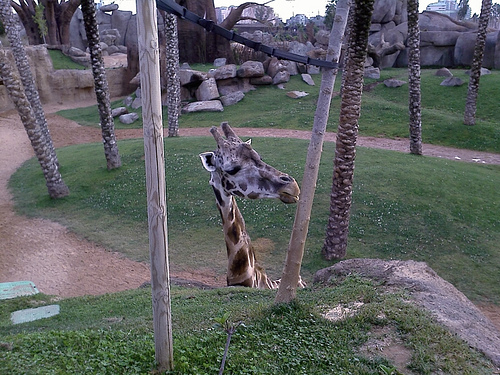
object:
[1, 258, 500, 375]
hill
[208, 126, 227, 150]
horn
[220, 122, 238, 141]
horn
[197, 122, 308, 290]
giraffe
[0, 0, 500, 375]
zoo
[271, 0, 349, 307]
tree trunk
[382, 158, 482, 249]
green grass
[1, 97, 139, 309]
path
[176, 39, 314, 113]
boulders/rocks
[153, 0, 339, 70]
black strap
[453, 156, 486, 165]
water puddle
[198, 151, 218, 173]
right ear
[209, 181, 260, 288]
neck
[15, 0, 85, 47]
tree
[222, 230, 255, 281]
brown spots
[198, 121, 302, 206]
giraffe's head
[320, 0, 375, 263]
trunk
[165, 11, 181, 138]
trunk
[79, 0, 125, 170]
trunk